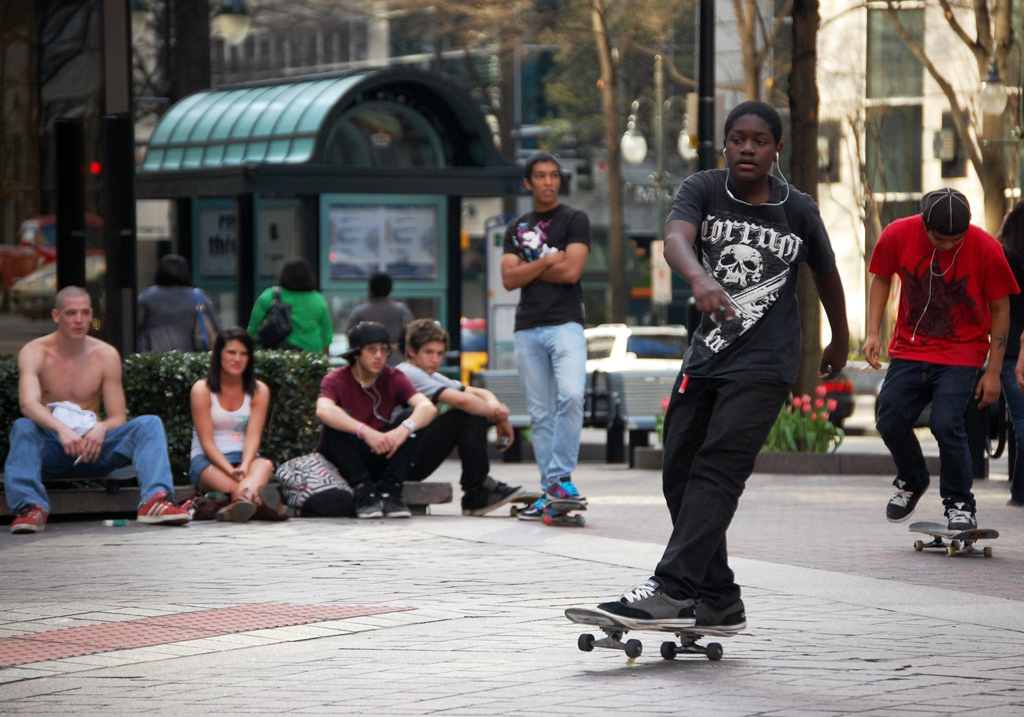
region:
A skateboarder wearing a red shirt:
[860, 188, 1016, 563]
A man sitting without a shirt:
[6, 289, 193, 536]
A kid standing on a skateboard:
[500, 159, 595, 530]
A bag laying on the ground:
[278, 454, 359, 516]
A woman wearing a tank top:
[183, 331, 297, 521]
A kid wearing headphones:
[313, 322, 437, 518]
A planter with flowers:
[765, 391, 889, 480]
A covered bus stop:
[137, 61, 529, 388]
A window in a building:
[863, 104, 922, 190]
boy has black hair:
[693, 107, 802, 188]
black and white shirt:
[654, 195, 817, 414]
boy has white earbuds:
[679, 112, 813, 195]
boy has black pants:
[657, 327, 771, 569]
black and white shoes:
[583, 570, 765, 621]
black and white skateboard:
[579, 565, 729, 619]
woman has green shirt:
[222, 284, 400, 367]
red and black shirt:
[872, 214, 990, 370]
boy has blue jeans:
[894, 357, 1000, 538]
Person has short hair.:
[720, 92, 787, 137]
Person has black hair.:
[718, 91, 796, 140]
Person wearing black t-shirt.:
[663, 138, 812, 383]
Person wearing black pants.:
[650, 354, 755, 590]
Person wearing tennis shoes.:
[609, 552, 762, 657]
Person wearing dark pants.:
[869, 356, 978, 506]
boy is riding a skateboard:
[570, 97, 861, 655]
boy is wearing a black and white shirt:
[665, 166, 840, 411]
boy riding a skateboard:
[858, 181, 1015, 567]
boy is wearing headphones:
[716, 131, 802, 214]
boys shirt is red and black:
[867, 207, 1020, 378]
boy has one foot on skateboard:
[503, 151, 592, 522]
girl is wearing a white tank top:
[181, 333, 290, 531]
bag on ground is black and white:
[276, 451, 362, 529]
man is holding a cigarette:
[2, 283, 196, 534]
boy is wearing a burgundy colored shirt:
[318, 321, 519, 533]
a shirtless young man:
[5, 286, 193, 534]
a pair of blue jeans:
[5, 415, 179, 508]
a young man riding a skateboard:
[566, 100, 852, 657]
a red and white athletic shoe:
[135, 497, 187, 527]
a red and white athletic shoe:
[8, 510, 46, 530]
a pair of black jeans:
[661, 374, 791, 609]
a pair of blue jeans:
[514, 326, 587, 491]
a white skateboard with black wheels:
[566, 604, 745, 663]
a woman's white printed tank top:
[191, 375, 256, 459]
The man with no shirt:
[6, 278, 187, 561]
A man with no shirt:
[3, 263, 203, 573]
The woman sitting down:
[163, 287, 325, 543]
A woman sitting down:
[161, 313, 307, 523]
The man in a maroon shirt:
[297, 282, 441, 521]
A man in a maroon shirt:
[306, 312, 436, 534]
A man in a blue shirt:
[386, 304, 522, 524]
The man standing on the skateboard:
[474, 160, 608, 540]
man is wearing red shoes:
[3, 284, 190, 535]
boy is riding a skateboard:
[556, 97, 857, 657]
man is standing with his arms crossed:
[498, 144, 597, 527]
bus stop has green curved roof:
[135, 66, 524, 395]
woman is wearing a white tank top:
[188, 325, 291, 525]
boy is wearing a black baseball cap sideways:
[316, 322, 440, 518]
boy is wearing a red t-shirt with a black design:
[862, 183, 1021, 548]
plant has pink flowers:
[659, 354, 844, 459]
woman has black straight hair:
[183, 327, 292, 525]